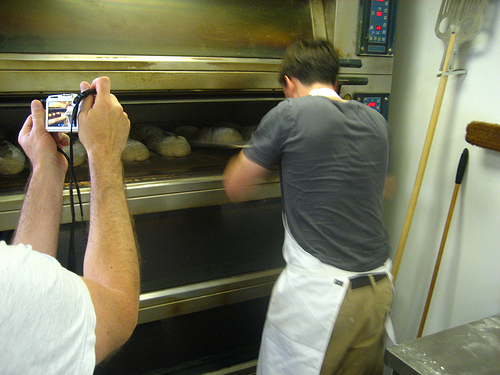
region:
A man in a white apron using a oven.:
[226, 32, 413, 371]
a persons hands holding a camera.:
[17, 79, 131, 163]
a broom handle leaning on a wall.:
[441, 126, 477, 301]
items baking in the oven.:
[114, 114, 201, 177]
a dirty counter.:
[373, 307, 485, 373]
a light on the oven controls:
[356, 83, 411, 136]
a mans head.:
[263, 34, 358, 109]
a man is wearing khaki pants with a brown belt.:
[307, 256, 386, 306]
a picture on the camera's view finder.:
[37, 92, 93, 141]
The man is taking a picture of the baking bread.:
[37, 90, 107, 134]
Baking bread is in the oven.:
[131, 101, 246, 174]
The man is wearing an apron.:
[256, 221, 387, 373]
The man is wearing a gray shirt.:
[241, 98, 408, 278]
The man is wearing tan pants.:
[286, 269, 406, 372]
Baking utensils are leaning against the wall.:
[396, 1, 499, 337]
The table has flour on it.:
[385, 306, 499, 374]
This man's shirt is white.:
[1, 242, 96, 374]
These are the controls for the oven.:
[345, 0, 398, 63]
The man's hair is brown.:
[273, 36, 345, 88]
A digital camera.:
[5, 80, 131, 175]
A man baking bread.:
[260, 40, 390, 360]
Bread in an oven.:
[130, 115, 230, 165]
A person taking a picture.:
[5, 75, 150, 370]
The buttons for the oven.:
[350, 0, 390, 55]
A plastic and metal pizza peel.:
[390, 0, 490, 270]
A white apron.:
[255, 215, 351, 372]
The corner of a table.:
[381, 300, 489, 371]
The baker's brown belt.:
[346, 265, 386, 290]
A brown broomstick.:
[408, 139, 473, 337]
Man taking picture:
[8, 78, 140, 370]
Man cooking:
[233, 65, 396, 367]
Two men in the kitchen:
[5, 38, 386, 364]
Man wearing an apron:
[221, 37, 407, 369]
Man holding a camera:
[7, 75, 142, 366]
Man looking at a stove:
[230, 54, 407, 369]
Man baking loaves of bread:
[230, 51, 392, 366]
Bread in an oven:
[133, 92, 223, 169]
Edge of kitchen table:
[386, 321, 494, 366]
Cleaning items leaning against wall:
[401, 24, 494, 311]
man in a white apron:
[220, 35, 390, 372]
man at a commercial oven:
[216, 31, 386, 366]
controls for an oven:
[352, 5, 392, 128]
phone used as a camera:
[40, 85, 85, 131]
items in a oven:
[128, 112, 224, 177]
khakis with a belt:
[255, 260, 405, 373]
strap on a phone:
[30, 75, 105, 271]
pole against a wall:
[405, 141, 475, 338]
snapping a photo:
[8, 75, 130, 166]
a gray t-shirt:
[238, 96, 403, 271]